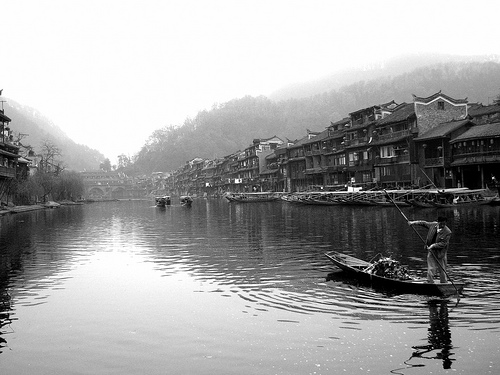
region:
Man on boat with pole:
[290, 191, 473, 322]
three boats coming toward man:
[145, 184, 202, 222]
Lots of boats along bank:
[231, 186, 498, 236]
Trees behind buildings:
[106, 49, 496, 209]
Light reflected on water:
[19, 206, 489, 374]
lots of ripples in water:
[218, 209, 485, 359]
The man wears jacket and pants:
[399, 203, 473, 313]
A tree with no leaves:
[28, 128, 68, 210]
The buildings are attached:
[263, 103, 490, 202]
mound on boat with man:
[321, 236, 476, 318]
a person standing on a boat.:
[305, 212, 461, 322]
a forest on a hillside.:
[116, 56, 498, 201]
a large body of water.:
[0, 200, 496, 371]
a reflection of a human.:
[416, 286, 456, 373]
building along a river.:
[152, 90, 497, 205]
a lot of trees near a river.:
[0, 108, 76, 207]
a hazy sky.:
[3, 1, 497, 171]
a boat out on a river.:
[182, 193, 206, 215]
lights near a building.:
[223, 178, 254, 190]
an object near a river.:
[323, 173, 390, 213]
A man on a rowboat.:
[321, 188, 468, 296]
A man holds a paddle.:
[384, 189, 468, 295]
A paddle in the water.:
[449, 289, 472, 311]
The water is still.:
[101, 228, 260, 359]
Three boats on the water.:
[149, 193, 195, 213]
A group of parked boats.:
[228, 189, 497, 203]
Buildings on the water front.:
[156, 95, 498, 202]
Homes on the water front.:
[0, 114, 42, 207]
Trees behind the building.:
[101, 108, 229, 168]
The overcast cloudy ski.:
[74, 62, 184, 126]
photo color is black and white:
[5, 7, 498, 370]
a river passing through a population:
[0, 209, 499, 373]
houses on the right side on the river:
[145, 88, 497, 193]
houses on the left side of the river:
[3, 111, 41, 209]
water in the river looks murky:
[0, 210, 491, 373]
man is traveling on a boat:
[319, 177, 476, 302]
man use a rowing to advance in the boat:
[319, 176, 476, 312]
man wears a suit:
[404, 201, 464, 303]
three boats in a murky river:
[144, 189, 196, 216]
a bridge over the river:
[71, 161, 149, 207]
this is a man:
[419, 211, 456, 277]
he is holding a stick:
[410, 205, 458, 282]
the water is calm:
[139, 234, 279, 368]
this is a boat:
[320, 250, 360, 269]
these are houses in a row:
[290, 104, 428, 184]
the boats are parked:
[225, 177, 362, 208]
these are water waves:
[249, 274, 332, 322]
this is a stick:
[382, 187, 400, 209]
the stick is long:
[444, 265, 459, 287]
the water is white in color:
[116, 33, 201, 95]